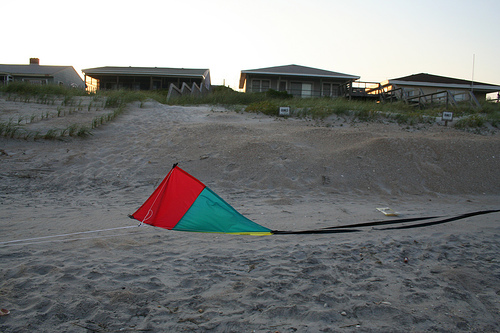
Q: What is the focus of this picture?
A: A kite.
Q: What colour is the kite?
A: Red, blue and yellow.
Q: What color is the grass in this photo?
A: Green.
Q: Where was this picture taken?
A: A beach.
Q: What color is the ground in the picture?
A: Tan.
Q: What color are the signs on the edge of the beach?
A: White.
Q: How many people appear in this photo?
A: Zero.